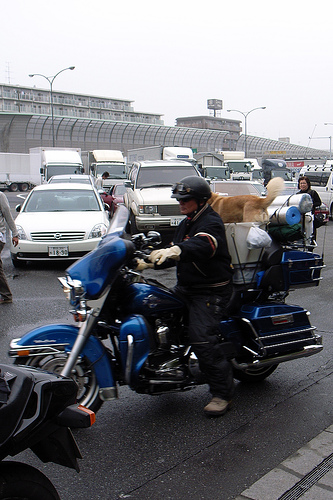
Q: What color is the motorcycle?
A: Blue.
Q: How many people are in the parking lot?
A: Two.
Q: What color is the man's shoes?
A: White.